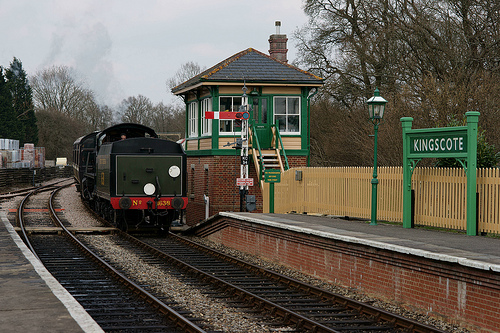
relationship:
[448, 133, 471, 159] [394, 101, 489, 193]
letter on sign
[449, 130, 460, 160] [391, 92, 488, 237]
letter on sign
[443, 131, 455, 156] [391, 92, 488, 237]
letter on sign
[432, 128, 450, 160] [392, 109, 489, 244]
letter on sign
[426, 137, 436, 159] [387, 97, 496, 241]
letter on sign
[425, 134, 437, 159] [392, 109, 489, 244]
letter on sign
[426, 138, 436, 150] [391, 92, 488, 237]
letter on sign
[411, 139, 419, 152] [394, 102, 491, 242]
letter on sign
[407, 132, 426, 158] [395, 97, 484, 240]
letter on sign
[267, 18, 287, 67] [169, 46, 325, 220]
chimney on top of train station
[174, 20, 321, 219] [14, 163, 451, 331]
train station by tracks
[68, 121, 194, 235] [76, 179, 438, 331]
train on tracks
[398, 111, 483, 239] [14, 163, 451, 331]
sign next to tracks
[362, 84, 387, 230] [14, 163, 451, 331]
light fixture next to tracks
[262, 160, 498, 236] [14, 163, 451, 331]
fence next to tracks